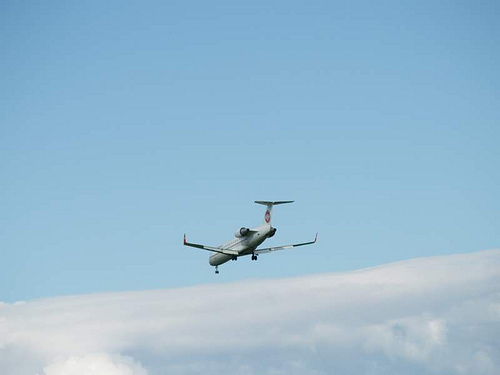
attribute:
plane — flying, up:
[183, 200, 318, 275]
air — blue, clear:
[2, 0, 499, 274]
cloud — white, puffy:
[1, 249, 498, 374]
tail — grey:
[254, 199, 294, 224]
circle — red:
[263, 213, 271, 224]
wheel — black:
[251, 253, 258, 261]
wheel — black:
[214, 268, 220, 274]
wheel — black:
[230, 255, 238, 262]